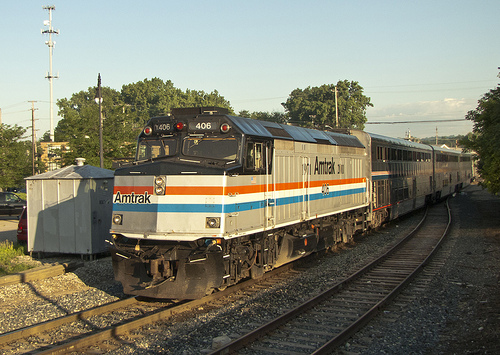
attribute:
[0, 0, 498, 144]
sky — blue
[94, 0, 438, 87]
sky — blue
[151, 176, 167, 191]
light — middle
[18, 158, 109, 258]
structure — gray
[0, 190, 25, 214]
truck — black, parked, nearby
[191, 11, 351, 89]
sky — blue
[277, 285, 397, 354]
tracks — clear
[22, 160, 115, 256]
building — small silver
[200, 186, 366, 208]
stripe — white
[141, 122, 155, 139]
round light — round red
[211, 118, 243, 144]
light — red,  right.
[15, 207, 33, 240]
vehicle — back end 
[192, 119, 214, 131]
number —  406, left.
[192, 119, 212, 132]
number 406 — number ,  right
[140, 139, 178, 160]
left window —  left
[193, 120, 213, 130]
numbers — white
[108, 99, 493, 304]
train — silver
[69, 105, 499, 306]
train — silver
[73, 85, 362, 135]
trees — green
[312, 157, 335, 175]
logo — black l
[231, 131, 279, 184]
paint — black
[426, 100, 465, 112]
clouds — white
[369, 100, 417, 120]
clouds — white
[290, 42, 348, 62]
clouds — white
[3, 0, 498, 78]
sky — blue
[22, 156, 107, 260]
shed — silver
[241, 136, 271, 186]
window — right side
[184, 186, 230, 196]
paint — orange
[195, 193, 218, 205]
paint — white